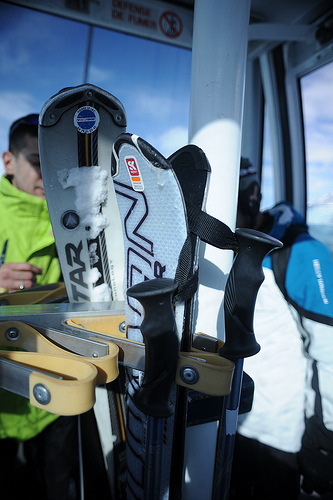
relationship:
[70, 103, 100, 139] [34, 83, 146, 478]
tag on ski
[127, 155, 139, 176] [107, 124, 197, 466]
box on ski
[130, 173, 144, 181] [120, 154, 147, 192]
box on tag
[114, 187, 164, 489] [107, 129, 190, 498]
writing on ski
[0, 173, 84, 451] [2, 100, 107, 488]
jacket on man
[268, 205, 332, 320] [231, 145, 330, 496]
jacket on man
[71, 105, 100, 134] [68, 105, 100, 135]
border on tag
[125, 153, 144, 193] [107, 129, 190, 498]
tag on end of ski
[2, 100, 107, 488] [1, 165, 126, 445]
man wearing jacket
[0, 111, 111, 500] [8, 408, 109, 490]
man wearing pants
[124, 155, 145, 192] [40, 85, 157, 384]
tag on skis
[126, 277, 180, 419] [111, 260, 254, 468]
grip of pole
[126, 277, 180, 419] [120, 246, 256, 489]
grip of pole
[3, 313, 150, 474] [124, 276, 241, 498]
slots for skis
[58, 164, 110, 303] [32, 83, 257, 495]
snow on skis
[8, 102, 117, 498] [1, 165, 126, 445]
he wearing jacket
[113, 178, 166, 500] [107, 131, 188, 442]
writing on ski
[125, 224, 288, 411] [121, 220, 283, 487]
handles on poles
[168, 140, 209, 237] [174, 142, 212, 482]
bottom of a ski